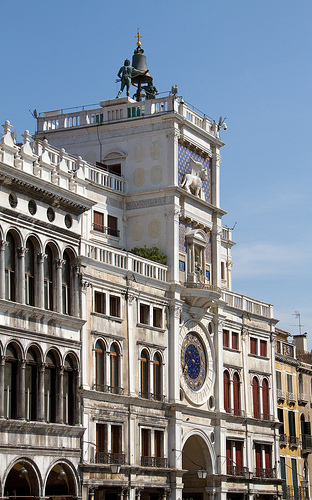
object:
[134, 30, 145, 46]
cross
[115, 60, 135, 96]
man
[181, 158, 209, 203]
animal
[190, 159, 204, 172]
wings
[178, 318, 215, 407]
round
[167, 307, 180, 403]
columns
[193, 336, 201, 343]
gold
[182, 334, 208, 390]
circle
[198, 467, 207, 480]
lantern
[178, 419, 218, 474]
archway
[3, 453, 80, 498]
arches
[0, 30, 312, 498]
building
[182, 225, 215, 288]
terrace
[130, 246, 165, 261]
tree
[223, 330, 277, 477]
windows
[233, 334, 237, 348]
red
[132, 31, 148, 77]
bell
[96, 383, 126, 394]
balcony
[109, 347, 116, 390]
pillars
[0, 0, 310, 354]
sky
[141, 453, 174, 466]
railing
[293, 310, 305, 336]
antenna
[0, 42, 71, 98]
blue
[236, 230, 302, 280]
clouds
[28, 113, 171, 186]
wall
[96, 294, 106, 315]
window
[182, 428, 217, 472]
arch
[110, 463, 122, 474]
light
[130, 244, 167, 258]
green